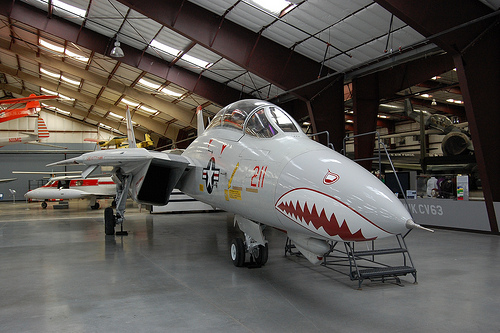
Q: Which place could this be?
A: It is a hangar.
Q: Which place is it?
A: It is a hangar.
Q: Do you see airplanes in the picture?
A: Yes, there is an airplane.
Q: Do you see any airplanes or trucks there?
A: Yes, there is an airplane.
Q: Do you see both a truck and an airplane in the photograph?
A: No, there is an airplane but no trucks.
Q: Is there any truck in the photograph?
A: No, there are no trucks.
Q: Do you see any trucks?
A: No, there are no trucks.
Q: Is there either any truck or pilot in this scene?
A: No, there are no trucks or pilots.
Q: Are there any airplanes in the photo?
A: Yes, there is an airplane.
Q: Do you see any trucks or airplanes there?
A: Yes, there is an airplane.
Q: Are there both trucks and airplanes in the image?
A: No, there is an airplane but no trucks.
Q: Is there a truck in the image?
A: No, there are no trucks.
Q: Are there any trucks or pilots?
A: No, there are no trucks or pilots.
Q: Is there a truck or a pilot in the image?
A: No, there are no trucks or pilots.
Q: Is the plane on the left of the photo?
A: Yes, the plane is on the left of the image.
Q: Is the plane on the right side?
A: No, the plane is on the left of the image.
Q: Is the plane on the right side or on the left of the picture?
A: The plane is on the left of the image.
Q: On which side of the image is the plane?
A: The plane is on the left of the image.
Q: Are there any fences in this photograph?
A: No, there are no fences.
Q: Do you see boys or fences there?
A: No, there are no fences or boys.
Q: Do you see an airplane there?
A: Yes, there is an airplane.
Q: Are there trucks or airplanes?
A: Yes, there is an airplane.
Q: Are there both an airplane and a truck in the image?
A: No, there is an airplane but no trucks.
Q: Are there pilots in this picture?
A: No, there are no pilots.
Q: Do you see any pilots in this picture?
A: No, there are no pilots.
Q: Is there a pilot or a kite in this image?
A: No, there are no pilots or kites.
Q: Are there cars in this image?
A: No, there are no cars.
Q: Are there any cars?
A: No, there are no cars.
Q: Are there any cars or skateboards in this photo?
A: No, there are no cars or skateboards.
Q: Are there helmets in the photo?
A: No, there are no helmets.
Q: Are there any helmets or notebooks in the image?
A: No, there are no helmets or notebooks.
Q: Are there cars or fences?
A: No, there are no fences or cars.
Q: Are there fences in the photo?
A: No, there are no fences.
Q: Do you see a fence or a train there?
A: No, there are no fences or trains.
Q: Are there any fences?
A: No, there are no fences.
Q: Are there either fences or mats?
A: No, there are no fences or mats.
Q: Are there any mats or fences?
A: No, there are no fences or mats.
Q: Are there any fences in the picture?
A: No, there are no fences.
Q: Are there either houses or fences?
A: No, there are no fences or houses.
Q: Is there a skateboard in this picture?
A: No, there are no skateboards.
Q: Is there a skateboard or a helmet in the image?
A: No, there are no skateboards or helmets.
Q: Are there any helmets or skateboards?
A: No, there are no skateboards or helmets.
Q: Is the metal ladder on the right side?
A: Yes, the ladder is on the right of the image.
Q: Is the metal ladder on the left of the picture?
A: No, the ladder is on the right of the image.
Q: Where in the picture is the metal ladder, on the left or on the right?
A: The ladder is on the right of the image.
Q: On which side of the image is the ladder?
A: The ladder is on the right of the image.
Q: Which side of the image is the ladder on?
A: The ladder is on the right of the image.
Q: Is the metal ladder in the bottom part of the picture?
A: Yes, the ladder is in the bottom of the image.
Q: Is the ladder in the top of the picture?
A: No, the ladder is in the bottom of the image.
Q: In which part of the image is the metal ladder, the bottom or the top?
A: The ladder is in the bottom of the image.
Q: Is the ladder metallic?
A: Yes, the ladder is metallic.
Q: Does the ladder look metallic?
A: Yes, the ladder is metallic.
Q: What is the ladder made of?
A: The ladder is made of metal.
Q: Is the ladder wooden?
A: No, the ladder is metallic.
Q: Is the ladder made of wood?
A: No, the ladder is made of metal.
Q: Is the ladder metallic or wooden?
A: The ladder is metallic.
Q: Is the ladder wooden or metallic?
A: The ladder is metallic.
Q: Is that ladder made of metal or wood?
A: The ladder is made of metal.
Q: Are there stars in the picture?
A: Yes, there is a star.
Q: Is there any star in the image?
A: Yes, there is a star.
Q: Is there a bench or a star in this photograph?
A: Yes, there is a star.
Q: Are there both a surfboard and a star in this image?
A: No, there is a star but no surfboards.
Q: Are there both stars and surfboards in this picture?
A: No, there is a star but no surfboards.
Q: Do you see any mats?
A: No, there are no mats.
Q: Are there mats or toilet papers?
A: No, there are no mats or toilet papers.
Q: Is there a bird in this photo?
A: No, there are no birds.